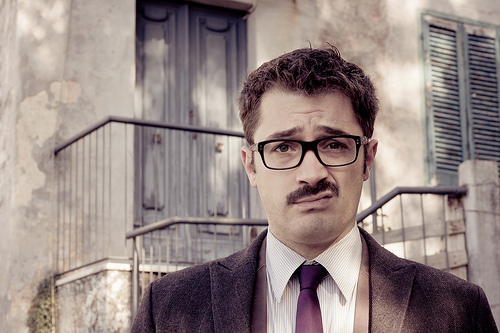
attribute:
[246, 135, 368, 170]
spectacle — edged, dark, rimmed, black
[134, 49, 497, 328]
man — nicely attired, dressed, unhappy about photo, in picture, facing camera, sneering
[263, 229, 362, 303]
collar — edged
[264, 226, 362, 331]
shirt — dress type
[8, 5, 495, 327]
building — old, partailly shaded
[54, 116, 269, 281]
railing — surrounding balcony, metal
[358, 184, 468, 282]
railing — metal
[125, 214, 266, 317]
railing — metal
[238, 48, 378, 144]
hair — a color, dark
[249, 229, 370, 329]
suit — black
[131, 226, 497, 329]
coat — smoky color, grey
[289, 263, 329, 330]
tie — purple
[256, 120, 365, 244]
face — giving a look, negative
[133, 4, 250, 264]
door — gray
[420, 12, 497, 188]
shutters — wooden, closed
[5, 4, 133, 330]
wall — in the background, stone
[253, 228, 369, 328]
jacket — purple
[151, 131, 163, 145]
handle — door type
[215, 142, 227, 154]
handle — door type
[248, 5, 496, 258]
wall — in the background, stone